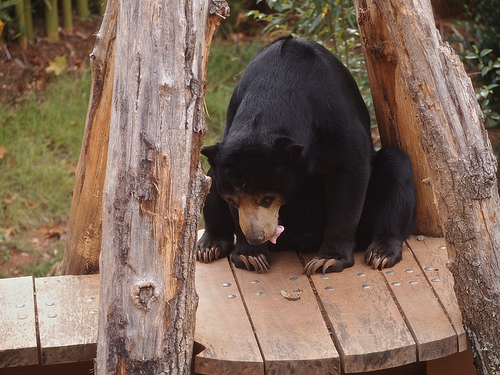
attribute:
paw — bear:
[301, 249, 354, 275]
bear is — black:
[187, 28, 425, 290]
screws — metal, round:
[221, 263, 450, 304]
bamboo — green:
[2, 2, 101, 38]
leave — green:
[461, 34, 495, 64]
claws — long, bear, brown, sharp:
[193, 241, 400, 278]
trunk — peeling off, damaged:
[95, 1, 212, 375]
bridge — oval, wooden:
[198, 222, 470, 370]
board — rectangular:
[234, 256, 345, 373]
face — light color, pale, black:
[230, 174, 285, 247]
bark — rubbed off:
[119, 8, 187, 373]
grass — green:
[5, 56, 91, 219]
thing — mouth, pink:
[268, 222, 288, 245]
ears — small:
[194, 132, 311, 160]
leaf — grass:
[36, 226, 70, 248]